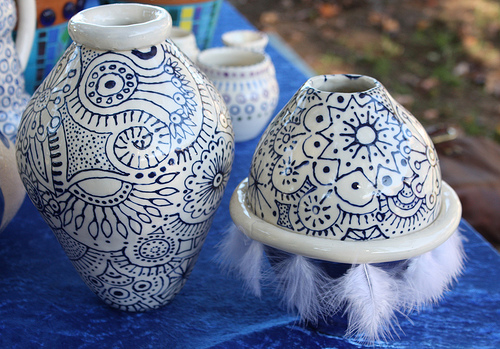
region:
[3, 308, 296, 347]
The tablecloth is the color blue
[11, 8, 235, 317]
The vase is sitting on the table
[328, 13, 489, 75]
The ground is the color brown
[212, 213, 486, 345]
The bottom of the vase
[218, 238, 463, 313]
The feathers on the vase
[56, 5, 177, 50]
The rim of the vase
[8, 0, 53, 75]
The handle on the vase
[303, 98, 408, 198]
The star shape on the vase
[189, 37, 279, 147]
The little jar on the table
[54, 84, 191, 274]
The vase has blue and white designs on it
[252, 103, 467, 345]
A white and black shell cover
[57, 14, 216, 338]
A white and black pot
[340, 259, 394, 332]
A white feather on a shell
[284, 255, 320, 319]
A white feather on a shell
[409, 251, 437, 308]
A white feather on a shell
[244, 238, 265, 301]
A white feather on a shell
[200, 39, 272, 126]
A white and black moulded pot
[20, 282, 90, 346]
A blue shinny table surface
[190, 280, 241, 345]
A blue shinny table surface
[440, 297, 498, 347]
A blue shinny table surface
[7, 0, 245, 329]
a vase over a blue table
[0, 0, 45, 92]
white handle of a vase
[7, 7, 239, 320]
blue designs on a vase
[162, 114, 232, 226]
a blue flower on a vase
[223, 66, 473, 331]
small vase with designs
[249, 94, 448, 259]
geometrical designs on a vase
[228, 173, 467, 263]
a ring in middle of vase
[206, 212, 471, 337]
feathers hanging from vase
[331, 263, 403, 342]
a white feather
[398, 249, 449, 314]
a white feather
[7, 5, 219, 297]
CERAMIC VASE IS DIAMOND SHAPED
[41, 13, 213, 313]
VASE IS WHITE AND BLUE IN COLOR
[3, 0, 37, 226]
CERAMIC PICTURE HAS A HANDLE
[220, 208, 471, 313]
CERAMIC ITEM HAS FEATHERS HANGING FROM IT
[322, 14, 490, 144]
BACKGROUND CONSIST OF GREEN AND BROWN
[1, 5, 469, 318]
CERAMIC ITEMS ARE ON A TABLE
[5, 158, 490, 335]
TABLE HAS A BLUE COVERING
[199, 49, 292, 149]
CERAMIC ITEM IS BLUE, PINK AND WHITE IN COLOR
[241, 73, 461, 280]
CERAMIC ITEM HAS A STAR PATTERN ON IT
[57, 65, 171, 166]
CERAMIC VASE HAS A SWIRL PATTERN ON THE TOP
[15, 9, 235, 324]
a vase over a table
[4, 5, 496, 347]
table covered with blue tablecloth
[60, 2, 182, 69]
top of vase is color white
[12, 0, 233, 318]
painting on a vase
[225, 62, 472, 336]
a vase with feathers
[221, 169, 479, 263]
a white ring around the vase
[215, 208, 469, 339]
white feathers around a ring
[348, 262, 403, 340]
a white feather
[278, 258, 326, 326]
a white feather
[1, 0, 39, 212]
a white handle of a vase